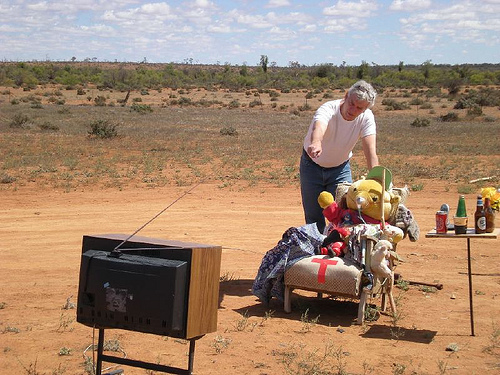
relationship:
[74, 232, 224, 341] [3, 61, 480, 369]
television on ground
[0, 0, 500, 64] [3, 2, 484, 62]
clouds in sky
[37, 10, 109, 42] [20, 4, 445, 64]
clouds in sky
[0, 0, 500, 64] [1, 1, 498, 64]
clouds in blue sky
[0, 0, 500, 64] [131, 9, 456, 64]
clouds in sky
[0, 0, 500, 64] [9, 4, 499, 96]
clouds in sky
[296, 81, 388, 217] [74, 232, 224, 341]
man pointing at television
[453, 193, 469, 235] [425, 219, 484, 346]
bottles on table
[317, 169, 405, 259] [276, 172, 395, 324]
animal on chair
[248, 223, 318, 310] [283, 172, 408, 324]
cloth on chair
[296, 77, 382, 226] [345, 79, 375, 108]
man with hair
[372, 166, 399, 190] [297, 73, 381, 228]
hat on man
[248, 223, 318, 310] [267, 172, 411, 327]
cloth on chair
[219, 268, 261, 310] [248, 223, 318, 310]
shadow of cloth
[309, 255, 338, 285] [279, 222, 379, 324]
cross on chair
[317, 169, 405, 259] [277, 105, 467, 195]
animal with shirt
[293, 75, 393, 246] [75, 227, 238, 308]
guy pointing to tv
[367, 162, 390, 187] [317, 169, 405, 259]
cap on animal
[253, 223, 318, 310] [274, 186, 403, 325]
cloth on chair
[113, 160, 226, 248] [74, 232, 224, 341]
antenna on television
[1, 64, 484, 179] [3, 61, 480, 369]
bushes on ground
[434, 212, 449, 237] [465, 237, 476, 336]
can on pole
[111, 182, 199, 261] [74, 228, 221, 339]
antenna on television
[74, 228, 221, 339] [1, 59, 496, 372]
television in desert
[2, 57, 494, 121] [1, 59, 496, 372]
foliage in desert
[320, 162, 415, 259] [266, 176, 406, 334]
animal in chair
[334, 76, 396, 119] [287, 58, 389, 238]
hair on man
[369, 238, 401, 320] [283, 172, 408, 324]
animal on chair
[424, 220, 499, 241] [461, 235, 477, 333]
table on pole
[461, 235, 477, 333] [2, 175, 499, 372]
pole in dirt